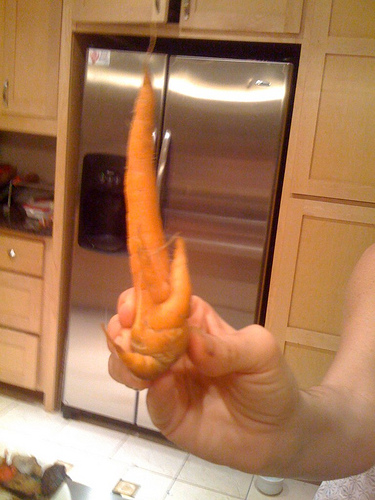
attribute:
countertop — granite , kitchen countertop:
[5, 211, 62, 243]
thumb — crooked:
[186, 325, 281, 380]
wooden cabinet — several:
[322, 4, 373, 53]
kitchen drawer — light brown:
[1, 229, 50, 279]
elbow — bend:
[146, 327, 356, 470]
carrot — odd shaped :
[104, 64, 194, 379]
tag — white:
[81, 48, 117, 69]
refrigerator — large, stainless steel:
[56, 50, 298, 419]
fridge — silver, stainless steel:
[75, 52, 258, 289]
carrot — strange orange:
[97, 76, 204, 351]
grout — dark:
[0, 451, 78, 498]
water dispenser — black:
[73, 141, 128, 252]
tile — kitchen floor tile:
[95, 435, 157, 498]